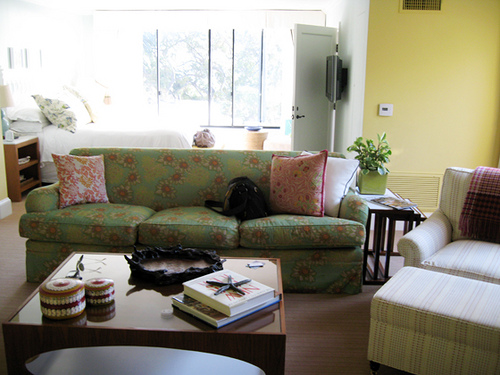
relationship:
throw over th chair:
[457, 167, 497, 237] [392, 158, 499, 288]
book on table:
[170, 269, 282, 328] [10, 242, 295, 372]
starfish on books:
[204, 272, 250, 303] [172, 265, 279, 343]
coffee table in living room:
[1, 251, 289, 372] [1, 2, 493, 365]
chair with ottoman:
[395, 164, 500, 284] [361, 265, 499, 372]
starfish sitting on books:
[204, 272, 250, 303] [177, 271, 277, 332]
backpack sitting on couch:
[204, 174, 267, 221] [15, 138, 373, 294]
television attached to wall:
[326, 53, 348, 106] [326, 2, 367, 172]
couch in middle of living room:
[15, 138, 373, 294] [0, 0, 499, 374]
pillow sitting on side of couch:
[265, 149, 329, 218] [22, 144, 376, 302]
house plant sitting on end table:
[345, 132, 392, 176] [344, 191, 427, 283]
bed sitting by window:
[0, 65, 226, 185] [46, 33, 280, 140]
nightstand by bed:
[8, 127, 48, 203] [6, 69, 193, 158]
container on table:
[92, 274, 119, 314] [10, 242, 295, 372]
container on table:
[35, 276, 80, 323] [10, 242, 295, 372]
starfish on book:
[204, 267, 249, 303] [175, 269, 282, 339]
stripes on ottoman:
[395, 273, 498, 314] [369, 267, 499, 375]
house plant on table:
[345, 132, 392, 176] [348, 189, 420, 272]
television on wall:
[321, 47, 348, 112] [333, 7, 362, 150]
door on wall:
[284, 13, 334, 154] [332, 11, 357, 156]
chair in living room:
[392, 158, 499, 288] [1, 2, 493, 365]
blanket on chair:
[452, 164, 499, 247] [392, 158, 499, 288]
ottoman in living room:
[369, 267, 499, 375] [1, 2, 493, 365]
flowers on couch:
[157, 151, 222, 187] [15, 138, 373, 294]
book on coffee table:
[170, 269, 282, 328] [1, 251, 289, 372]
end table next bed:
[4, 131, 42, 201] [12, 116, 192, 156]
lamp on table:
[0, 80, 18, 139] [1, 144, 41, 202]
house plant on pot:
[345, 132, 392, 176] [355, 169, 391, 199]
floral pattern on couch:
[144, 145, 224, 195] [15, 138, 373, 294]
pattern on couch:
[153, 147, 223, 181] [15, 138, 373, 294]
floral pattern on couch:
[26, 216, 60, 221] [15, 138, 373, 294]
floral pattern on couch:
[108, 202, 135, 218] [15, 138, 373, 294]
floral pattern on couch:
[232, 167, 261, 192] [15, 138, 373, 294]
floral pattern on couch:
[153, 176, 173, 192] [15, 138, 373, 294]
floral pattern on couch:
[315, 224, 345, 245] [15, 138, 373, 294]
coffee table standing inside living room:
[1, 251, 289, 372] [1, 2, 493, 365]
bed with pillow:
[0, 51, 226, 152] [27, 78, 98, 129]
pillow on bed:
[27, 78, 98, 129] [0, 51, 226, 152]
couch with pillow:
[18, 145, 369, 295] [265, 152, 334, 213]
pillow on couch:
[265, 152, 334, 213] [18, 145, 369, 295]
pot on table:
[353, 162, 394, 195] [354, 183, 427, 240]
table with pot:
[354, 183, 427, 240] [353, 162, 394, 195]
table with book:
[8, 234, 302, 365] [170, 269, 282, 328]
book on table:
[170, 269, 282, 328] [8, 234, 302, 365]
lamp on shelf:
[0, 80, 18, 139] [13, 153, 43, 172]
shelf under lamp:
[13, 153, 43, 172] [0, 80, 18, 139]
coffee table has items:
[6, 213, 307, 373] [28, 252, 125, 327]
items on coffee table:
[28, 252, 125, 327] [6, 213, 307, 373]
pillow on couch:
[265, 149, 329, 218] [18, 145, 369, 295]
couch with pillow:
[18, 145, 369, 295] [265, 149, 329, 218]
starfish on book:
[204, 272, 250, 303] [170, 269, 282, 328]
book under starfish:
[170, 269, 282, 328] [204, 272, 250, 303]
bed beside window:
[0, 65, 226, 185] [99, 5, 298, 136]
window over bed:
[99, 5, 298, 136] [0, 65, 226, 185]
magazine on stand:
[376, 194, 411, 215] [363, 200, 411, 281]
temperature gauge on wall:
[379, 101, 395, 116] [352, 0, 491, 199]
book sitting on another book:
[187, 257, 276, 314] [171, 286, 291, 333]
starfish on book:
[204, 272, 250, 303] [192, 260, 282, 306]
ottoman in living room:
[369, 260, 499, 368] [1, 2, 493, 365]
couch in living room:
[18, 145, 369, 295] [1, 2, 493, 365]